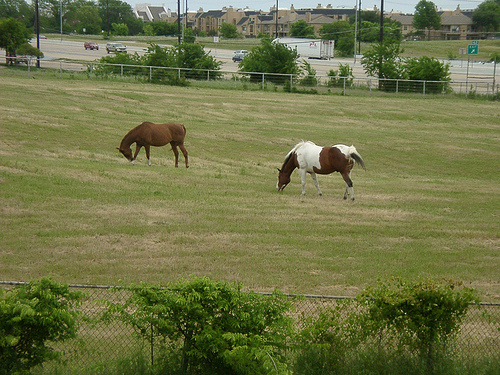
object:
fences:
[1, 275, 500, 368]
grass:
[354, 234, 496, 277]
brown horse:
[117, 120, 190, 168]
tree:
[1, 2, 19, 66]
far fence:
[344, 77, 489, 95]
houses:
[199, 9, 224, 33]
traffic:
[68, 41, 130, 54]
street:
[45, 41, 82, 55]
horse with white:
[299, 146, 317, 167]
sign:
[467, 40, 479, 55]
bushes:
[235, 42, 300, 81]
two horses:
[117, 121, 367, 201]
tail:
[349, 147, 366, 171]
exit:
[467, 42, 477, 55]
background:
[5, 0, 497, 98]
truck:
[262, 35, 334, 61]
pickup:
[106, 43, 131, 55]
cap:
[107, 42, 127, 55]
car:
[82, 41, 98, 52]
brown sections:
[145, 200, 185, 222]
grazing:
[115, 144, 135, 162]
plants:
[385, 278, 473, 372]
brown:
[323, 152, 339, 173]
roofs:
[292, 9, 358, 16]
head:
[115, 146, 136, 160]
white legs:
[298, 169, 309, 197]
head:
[275, 168, 296, 192]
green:
[108, 350, 142, 375]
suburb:
[195, 5, 233, 36]